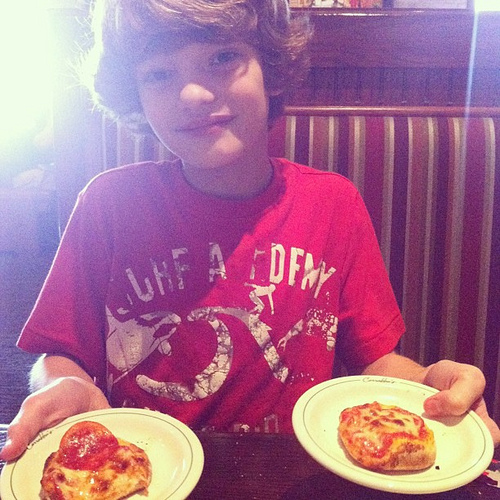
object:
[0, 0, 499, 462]
boy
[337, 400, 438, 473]
pizza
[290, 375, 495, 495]
plate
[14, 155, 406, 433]
shirt